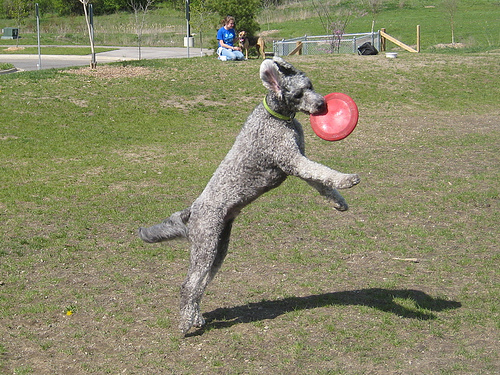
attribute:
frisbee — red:
[308, 90, 356, 139]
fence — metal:
[265, 25, 390, 63]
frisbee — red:
[313, 90, 373, 144]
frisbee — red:
[299, 83, 375, 154]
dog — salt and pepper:
[140, 56, 360, 337]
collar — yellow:
[257, 96, 297, 121]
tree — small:
[316, 6, 366, 60]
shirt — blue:
[216, 26, 247, 56]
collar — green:
[238, 76, 341, 181]